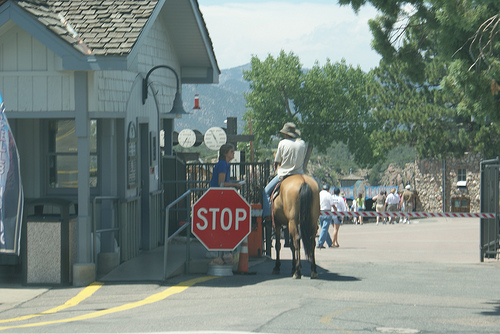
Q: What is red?
A: Stop sign.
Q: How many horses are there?
A: One.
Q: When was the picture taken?
A: Daytime.